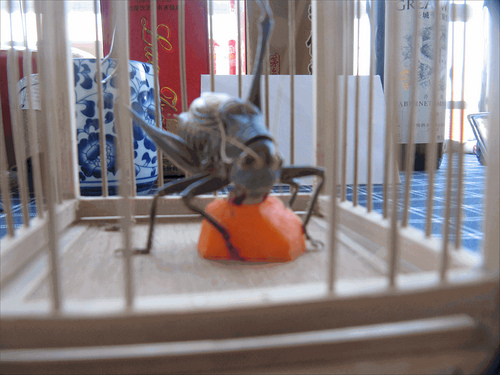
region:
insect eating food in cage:
[33, 2, 352, 274]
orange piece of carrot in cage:
[182, 178, 319, 265]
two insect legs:
[108, 164, 244, 273]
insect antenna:
[154, 96, 266, 173]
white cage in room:
[1, 1, 498, 372]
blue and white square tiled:
[353, 150, 498, 261]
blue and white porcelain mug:
[51, 50, 164, 199]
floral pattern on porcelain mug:
[71, 106, 141, 183]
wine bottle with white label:
[364, 1, 457, 176]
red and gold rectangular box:
[97, 1, 221, 183]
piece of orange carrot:
[191, 195, 314, 256]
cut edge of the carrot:
[276, 232, 311, 260]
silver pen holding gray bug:
[46, 76, 487, 288]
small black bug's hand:
[171, 180, 245, 273]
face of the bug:
[225, 130, 283, 218]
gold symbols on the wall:
[134, 13, 195, 89]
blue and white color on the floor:
[391, 177, 477, 227]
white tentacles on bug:
[207, 123, 262, 175]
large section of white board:
[204, 63, 442, 199]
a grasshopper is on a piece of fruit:
[113, 4, 336, 261]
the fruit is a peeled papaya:
[197, 191, 311, 263]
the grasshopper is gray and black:
[101, 7, 328, 265]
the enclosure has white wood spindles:
[3, 2, 496, 274]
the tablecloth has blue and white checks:
[9, 146, 498, 299]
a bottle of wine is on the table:
[368, 0, 450, 170]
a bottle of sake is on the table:
[243, 4, 348, 98]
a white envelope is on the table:
[196, 70, 399, 187]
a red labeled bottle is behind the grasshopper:
[96, 0, 213, 187]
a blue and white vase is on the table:
[58, 56, 160, 197]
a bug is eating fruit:
[157, 85, 416, 309]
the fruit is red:
[165, 102, 350, 338]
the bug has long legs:
[146, 158, 360, 228]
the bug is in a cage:
[12, 156, 433, 361]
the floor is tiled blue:
[374, 171, 466, 241]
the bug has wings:
[143, 135, 425, 251]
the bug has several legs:
[92, 37, 482, 225]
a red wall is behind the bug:
[114, 20, 297, 167]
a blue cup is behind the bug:
[47, 50, 257, 225]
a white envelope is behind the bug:
[240, 37, 460, 247]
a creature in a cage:
[67, 41, 401, 351]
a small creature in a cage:
[104, 50, 414, 365]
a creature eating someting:
[117, 45, 462, 347]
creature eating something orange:
[132, 101, 312, 323]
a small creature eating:
[47, 70, 396, 364]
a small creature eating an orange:
[107, 70, 387, 287]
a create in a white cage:
[18, 31, 489, 351]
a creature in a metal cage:
[44, 36, 496, 286]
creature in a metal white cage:
[29, 55, 415, 373]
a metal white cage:
[69, 68, 492, 327]